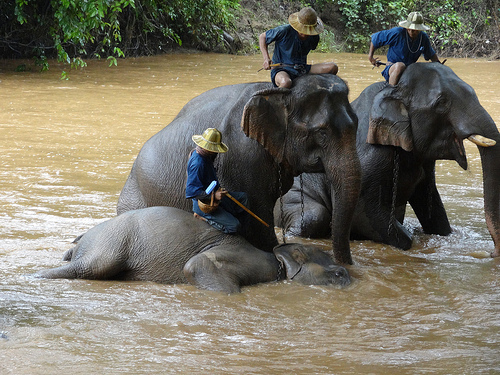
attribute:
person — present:
[368, 12, 442, 86]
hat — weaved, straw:
[397, 11, 430, 32]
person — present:
[258, 6, 338, 88]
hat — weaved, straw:
[286, 7, 323, 36]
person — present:
[185, 127, 250, 233]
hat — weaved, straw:
[190, 127, 228, 155]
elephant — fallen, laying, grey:
[38, 204, 354, 294]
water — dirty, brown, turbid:
[1, 51, 499, 374]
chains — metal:
[386, 145, 436, 242]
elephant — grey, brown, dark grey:
[117, 73, 362, 265]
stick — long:
[220, 187, 272, 228]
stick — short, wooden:
[257, 62, 282, 73]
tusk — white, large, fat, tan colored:
[468, 133, 496, 148]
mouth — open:
[450, 129, 480, 171]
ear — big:
[273, 242, 309, 280]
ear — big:
[366, 86, 413, 152]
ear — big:
[239, 89, 289, 165]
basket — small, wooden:
[198, 191, 219, 215]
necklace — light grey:
[404, 31, 424, 55]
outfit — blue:
[372, 28, 436, 81]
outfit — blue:
[265, 24, 319, 87]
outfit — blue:
[185, 152, 249, 233]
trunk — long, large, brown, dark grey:
[472, 107, 498, 258]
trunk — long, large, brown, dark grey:
[319, 152, 361, 265]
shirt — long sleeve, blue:
[185, 152, 221, 201]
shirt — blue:
[372, 27, 435, 65]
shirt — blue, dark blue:
[264, 27, 318, 67]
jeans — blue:
[192, 191, 249, 235]